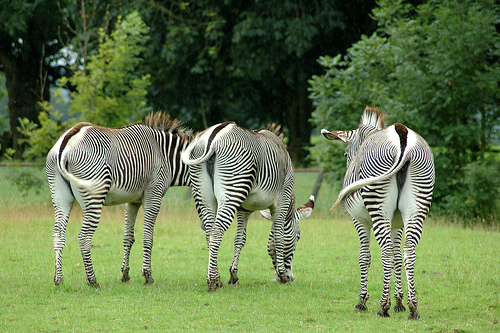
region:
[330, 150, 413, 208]
white tail of zebra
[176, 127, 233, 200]
white tail of middle zebra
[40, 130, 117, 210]
white tail of left zebra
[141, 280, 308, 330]
green grass under zebra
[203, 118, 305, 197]
black and white stripes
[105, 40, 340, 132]
trees in the background of photo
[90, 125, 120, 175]
black and white prints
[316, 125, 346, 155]
left ear of zebra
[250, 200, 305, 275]
right arm of zebra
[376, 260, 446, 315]
back leg of zebra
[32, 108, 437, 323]
three zebras standing around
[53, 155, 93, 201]
a tail of the zebra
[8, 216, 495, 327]
the grass the zebras are sitting on and eating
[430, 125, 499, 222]
a green leafy bush by the zebra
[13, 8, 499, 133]
assorted green leafy plants in the background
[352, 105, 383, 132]
the mane of a zebra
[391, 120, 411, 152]
a long black stripe on the back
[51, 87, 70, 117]
a patch of blue in the background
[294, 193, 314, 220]
an ear on the zebra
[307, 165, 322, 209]
the trunk of a tree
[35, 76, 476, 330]
zebras in a field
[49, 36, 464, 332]
three zebras in a field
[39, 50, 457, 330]
zebras standing in a field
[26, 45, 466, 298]
three zebras standing in a field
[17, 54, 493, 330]
zebra butts in field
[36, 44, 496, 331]
three zebra's butts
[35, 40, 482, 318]
zebras in a green field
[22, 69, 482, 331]
three zebras in a green field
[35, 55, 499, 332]
a zebra eating the grass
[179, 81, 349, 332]
zebra eatting the green grass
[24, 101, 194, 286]
black and white striped zebra grazing on grass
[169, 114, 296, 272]
black and white striped zebra grazing on grass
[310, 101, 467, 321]
black and white striped zebra grazing on grass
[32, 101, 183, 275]
black and white striped zebra grazing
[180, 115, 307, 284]
black and white striped zebra grazing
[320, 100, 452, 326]
black and white striped zebra grazing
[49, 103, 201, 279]
black and white striped zebra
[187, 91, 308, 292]
black and white striped zebra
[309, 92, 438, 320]
black and white striped zebra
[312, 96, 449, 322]
zebra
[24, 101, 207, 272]
black and white striped grazing zebra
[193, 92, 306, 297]
black and white striped grazing zebra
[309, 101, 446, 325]
black and white striped grazing zebra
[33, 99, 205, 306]
black and white zebra eating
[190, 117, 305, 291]
black and white zebra eating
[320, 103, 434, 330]
black and white zebra eating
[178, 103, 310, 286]
zebra eating